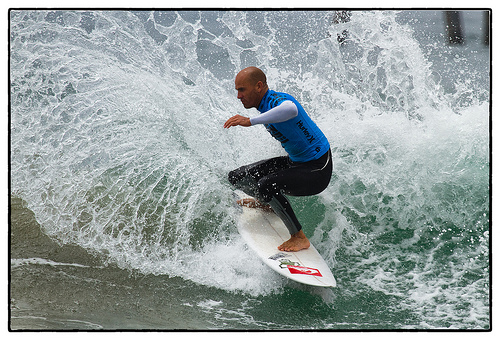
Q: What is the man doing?
A: Surfing.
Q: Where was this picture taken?
A: By a large body of water.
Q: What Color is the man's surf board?
A: White.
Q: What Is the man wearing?
A: A wetsuit.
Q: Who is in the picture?
A: A surfer.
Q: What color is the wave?
A: White.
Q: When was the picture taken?
A: Daytime.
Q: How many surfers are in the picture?
A: 1.